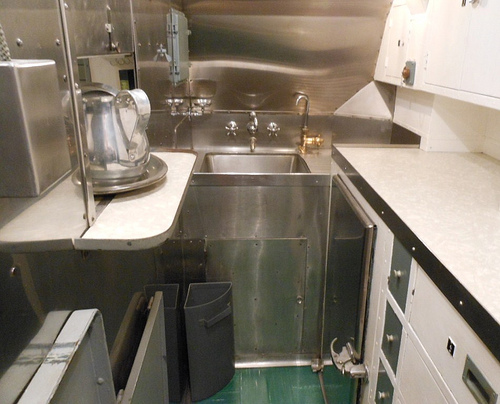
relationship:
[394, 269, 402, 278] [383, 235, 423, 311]
drawer pull on drawer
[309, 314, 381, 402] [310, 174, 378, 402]
handle on refrigerator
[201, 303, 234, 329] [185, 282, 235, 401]
handle on bin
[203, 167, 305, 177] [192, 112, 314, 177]
edge of sink